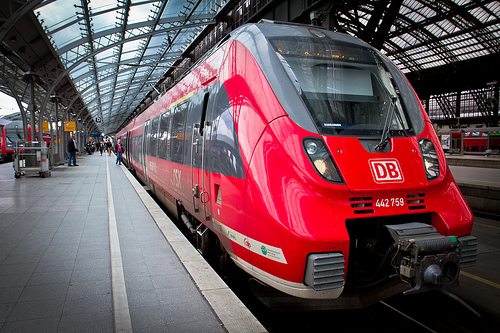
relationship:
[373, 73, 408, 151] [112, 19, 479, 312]
wiper on red train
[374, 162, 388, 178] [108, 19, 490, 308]
letter on train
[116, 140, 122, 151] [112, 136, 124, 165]
shirt on person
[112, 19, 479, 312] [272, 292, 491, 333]
red train on top of train tracks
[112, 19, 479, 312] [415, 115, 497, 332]
red train on tracks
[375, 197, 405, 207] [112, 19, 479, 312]
white number on red train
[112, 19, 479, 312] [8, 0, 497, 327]
red train at train station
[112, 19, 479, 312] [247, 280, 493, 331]
red train on track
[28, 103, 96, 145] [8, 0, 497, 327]
signs in train station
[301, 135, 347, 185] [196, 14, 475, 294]
light on train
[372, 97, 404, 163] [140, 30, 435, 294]
wiper on train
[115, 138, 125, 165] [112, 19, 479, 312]
passenger by red train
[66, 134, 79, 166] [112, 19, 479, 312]
people by red train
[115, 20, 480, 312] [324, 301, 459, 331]
red train on tracks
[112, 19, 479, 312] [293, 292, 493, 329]
red train on train tracks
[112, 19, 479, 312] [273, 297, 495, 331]
red train on track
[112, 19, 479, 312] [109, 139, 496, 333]
red train on tracks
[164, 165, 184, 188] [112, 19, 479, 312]
letters on red train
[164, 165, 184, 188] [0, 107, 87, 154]
letters on train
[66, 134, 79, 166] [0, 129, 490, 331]
people on platform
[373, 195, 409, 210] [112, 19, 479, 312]
white numbers on red train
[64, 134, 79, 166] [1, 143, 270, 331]
people on platform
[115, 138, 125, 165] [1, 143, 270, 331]
passenger on platform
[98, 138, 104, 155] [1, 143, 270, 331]
people on platform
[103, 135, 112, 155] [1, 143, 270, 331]
people on platform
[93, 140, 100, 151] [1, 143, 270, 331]
people on platform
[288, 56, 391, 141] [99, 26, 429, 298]
wind shield on train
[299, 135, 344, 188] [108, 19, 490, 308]
light on train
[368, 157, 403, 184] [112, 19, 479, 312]
decal on red train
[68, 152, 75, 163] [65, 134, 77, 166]
jeans on person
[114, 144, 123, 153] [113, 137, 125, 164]
shirt on person